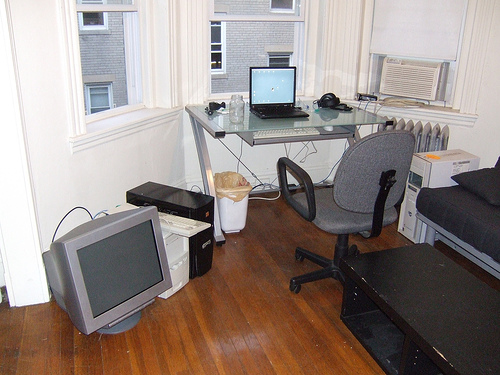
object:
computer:
[396, 149, 481, 245]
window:
[205, 0, 317, 98]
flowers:
[391, 147, 479, 248]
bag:
[213, 171, 253, 203]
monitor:
[71, 219, 172, 323]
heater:
[370, 50, 453, 104]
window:
[70, 0, 165, 122]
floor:
[0, 189, 397, 375]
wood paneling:
[130, 286, 275, 375]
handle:
[274, 157, 316, 220]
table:
[328, 161, 500, 371]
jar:
[227, 94, 245, 124]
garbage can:
[214, 169, 251, 235]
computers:
[93, 180, 216, 304]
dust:
[0, 195, 412, 372]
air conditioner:
[378, 57, 448, 102]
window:
[355, 0, 469, 112]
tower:
[395, 147, 484, 243]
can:
[211, 170, 252, 236]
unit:
[374, 51, 449, 104]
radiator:
[375, 116, 451, 159]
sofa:
[419, 158, 500, 287]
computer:
[249, 65, 309, 120]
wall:
[366, 91, 496, 141]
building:
[80, 25, 126, 110]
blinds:
[361, 0, 476, 108]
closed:
[358, 24, 474, 68]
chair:
[277, 129, 417, 294]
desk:
[178, 99, 392, 247]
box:
[336, 230, 500, 375]